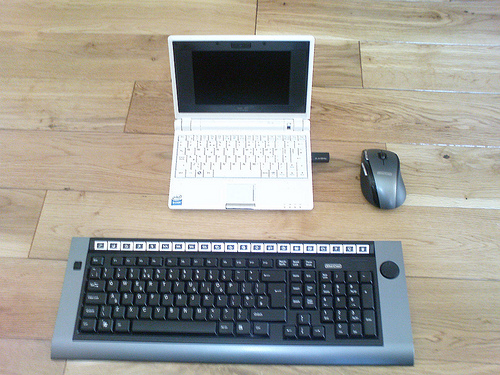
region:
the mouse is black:
[350, 101, 434, 277]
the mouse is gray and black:
[353, 95, 398, 256]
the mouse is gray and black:
[320, 55, 416, 245]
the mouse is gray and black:
[327, 111, 429, 353]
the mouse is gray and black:
[343, 136, 408, 281]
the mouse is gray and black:
[356, 160, 461, 276]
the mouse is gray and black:
[308, 151, 395, 296]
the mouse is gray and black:
[369, 115, 426, 271]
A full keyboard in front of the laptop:
[60, 231, 422, 366]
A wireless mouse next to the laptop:
[354, 145, 414, 210]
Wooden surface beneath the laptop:
[323, 5, 490, 141]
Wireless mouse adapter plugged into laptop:
[309, 147, 332, 164]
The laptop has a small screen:
[175, 40, 307, 112]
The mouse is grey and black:
[356, 145, 408, 208]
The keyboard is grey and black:
[57, 235, 417, 365]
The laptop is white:
[176, 119, 313, 209]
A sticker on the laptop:
[170, 193, 187, 212]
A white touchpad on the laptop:
[224, 181, 256, 210]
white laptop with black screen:
[134, 40, 316, 207]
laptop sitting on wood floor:
[103, 159, 210, 204]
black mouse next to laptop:
[345, 135, 414, 213]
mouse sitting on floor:
[357, 132, 409, 213]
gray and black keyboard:
[68, 218, 182, 312]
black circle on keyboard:
[359, 256, 422, 304]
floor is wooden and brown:
[364, 43, 477, 134]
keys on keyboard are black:
[101, 260, 207, 321]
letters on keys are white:
[121, 266, 223, 320]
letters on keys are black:
[216, 140, 280, 165]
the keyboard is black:
[144, 286, 321, 350]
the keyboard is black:
[177, 275, 279, 363]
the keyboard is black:
[121, 198, 298, 320]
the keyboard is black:
[245, 288, 373, 355]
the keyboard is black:
[140, 227, 272, 346]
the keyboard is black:
[254, 323, 307, 368]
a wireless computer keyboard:
[45, 234, 420, 364]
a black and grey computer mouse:
[360, 139, 405, 213]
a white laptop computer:
[156, 29, 321, 216]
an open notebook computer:
[155, 25, 317, 213]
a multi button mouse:
[353, 140, 405, 212]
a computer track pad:
[223, 180, 253, 204]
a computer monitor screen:
[168, 37, 306, 114]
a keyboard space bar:
[128, 317, 220, 338]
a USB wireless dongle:
[308, 147, 330, 164]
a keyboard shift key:
[248, 306, 285, 322]